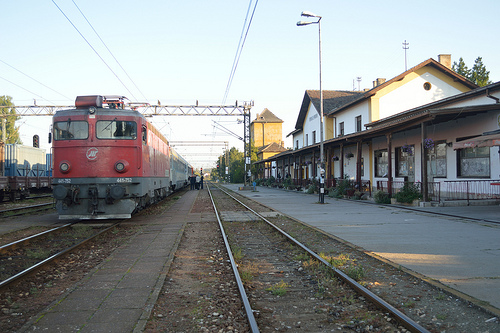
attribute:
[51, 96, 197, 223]
train — red, stopped, present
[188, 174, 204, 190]
people — standing, waiting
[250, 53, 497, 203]
station — yellow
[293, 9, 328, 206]
light pole — tall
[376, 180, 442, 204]
railing — present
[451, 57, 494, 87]
trees — green, present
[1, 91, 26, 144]
tree — green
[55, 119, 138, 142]
windows — large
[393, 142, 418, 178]
window — present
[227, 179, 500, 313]
pavement — present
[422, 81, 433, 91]
window — round, small